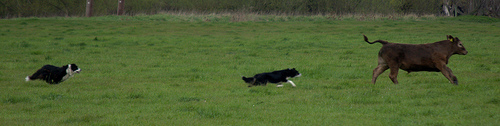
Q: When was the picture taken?
A: During the day.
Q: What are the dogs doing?
A: Chasing an animal.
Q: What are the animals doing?
A: Running.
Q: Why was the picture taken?
A: To capture the animals running.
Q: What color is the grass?
A: Green.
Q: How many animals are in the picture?
A: Three.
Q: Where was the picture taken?
A: In a field.